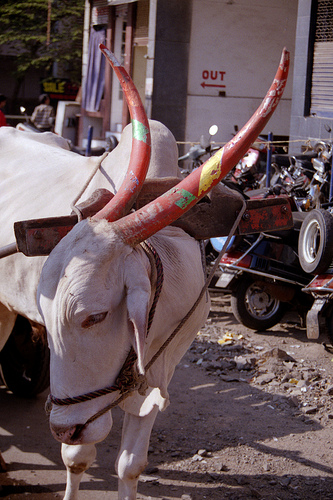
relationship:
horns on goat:
[97, 41, 332, 231] [1, 129, 210, 497]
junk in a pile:
[266, 160, 331, 198] [260, 140, 332, 257]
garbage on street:
[216, 333, 276, 377] [188, 388, 313, 495]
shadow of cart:
[176, 368, 277, 441] [1, 318, 46, 394]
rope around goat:
[121, 241, 171, 389] [1, 129, 210, 497]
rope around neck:
[121, 241, 171, 389] [123, 236, 168, 415]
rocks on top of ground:
[188, 445, 220, 463] [193, 429, 332, 494]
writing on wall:
[200, 68, 230, 83] [214, 19, 274, 66]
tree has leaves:
[11, 5, 56, 106] [4, 4, 37, 23]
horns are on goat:
[97, 41, 332, 231] [1, 129, 210, 497]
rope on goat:
[121, 241, 171, 389] [1, 129, 210, 497]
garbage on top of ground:
[216, 333, 276, 377] [193, 429, 332, 494]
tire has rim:
[295, 208, 331, 280] [305, 222, 321, 262]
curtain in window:
[316, 12, 332, 102] [303, 2, 331, 126]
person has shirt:
[1, 90, 13, 129] [2, 115, 8, 127]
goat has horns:
[1, 129, 210, 497] [97, 41, 332, 231]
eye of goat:
[82, 311, 108, 325] [1, 129, 210, 497]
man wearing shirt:
[33, 94, 58, 133] [37, 108, 55, 131]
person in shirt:
[1, 90, 13, 129] [2, 115, 8, 127]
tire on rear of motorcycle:
[230, 281, 285, 330] [216, 201, 318, 281]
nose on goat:
[49, 422, 82, 449] [1, 129, 210, 497]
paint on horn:
[202, 155, 222, 189] [163, 52, 305, 240]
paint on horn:
[170, 193, 195, 209] [163, 52, 305, 240]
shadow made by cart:
[176, 368, 277, 441] [1, 318, 46, 394]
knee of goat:
[116, 456, 143, 497] [1, 129, 210, 497]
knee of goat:
[63, 448, 90, 480] [1, 129, 210, 497]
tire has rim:
[230, 281, 285, 330] [248, 287, 273, 315]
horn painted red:
[163, 52, 305, 240] [226, 141, 249, 165]